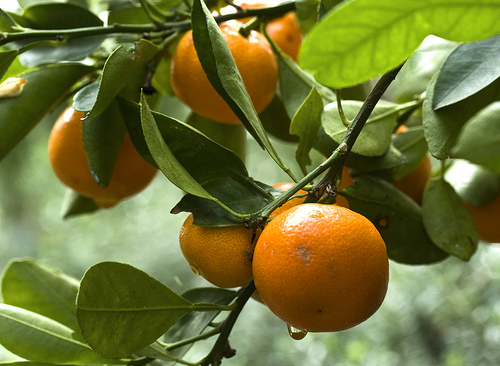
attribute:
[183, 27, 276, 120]
fruit — orange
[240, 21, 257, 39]
stem — long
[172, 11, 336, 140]
orange — ripe, fresh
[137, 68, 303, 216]
leaves — green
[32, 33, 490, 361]
tree — orange, green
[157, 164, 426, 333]
oranges — ripe, hanging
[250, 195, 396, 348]
orange — fresh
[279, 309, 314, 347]
water — dropping, drop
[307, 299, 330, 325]
spot — black, brown